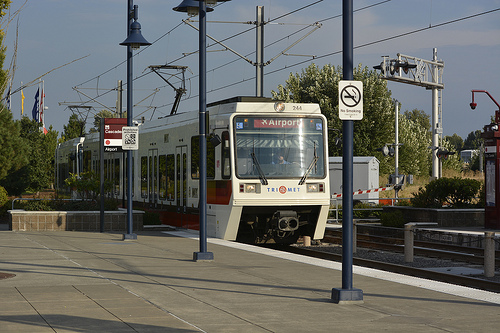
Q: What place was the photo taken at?
A: It was taken at the pavement.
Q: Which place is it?
A: It is a pavement.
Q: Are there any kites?
A: No, there are no kites.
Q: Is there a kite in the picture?
A: No, there are no kites.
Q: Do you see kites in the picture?
A: No, there are no kites.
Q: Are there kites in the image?
A: No, there are no kites.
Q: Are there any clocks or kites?
A: No, there are no kites or clocks.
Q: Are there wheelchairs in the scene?
A: No, there are no wheelchairs.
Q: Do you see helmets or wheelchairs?
A: No, there are no wheelchairs or helmets.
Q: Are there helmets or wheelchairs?
A: No, there are no wheelchairs or helmets.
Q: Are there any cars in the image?
A: No, there are no cars.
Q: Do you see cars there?
A: No, there are no cars.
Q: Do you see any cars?
A: No, there are no cars.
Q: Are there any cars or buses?
A: No, there are no cars or buses.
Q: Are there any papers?
A: No, there are no papers.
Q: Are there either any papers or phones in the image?
A: No, there are no papers or phones.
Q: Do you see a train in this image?
A: Yes, there is a train.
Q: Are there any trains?
A: Yes, there is a train.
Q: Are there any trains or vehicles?
A: Yes, there is a train.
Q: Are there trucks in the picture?
A: No, there are no trucks.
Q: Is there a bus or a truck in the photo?
A: No, there are no trucks or buses.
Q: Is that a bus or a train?
A: That is a train.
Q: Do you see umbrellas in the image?
A: No, there are no umbrellas.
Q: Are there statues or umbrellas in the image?
A: No, there are no umbrellas or statues.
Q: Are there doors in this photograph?
A: Yes, there are doors.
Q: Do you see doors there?
A: Yes, there are doors.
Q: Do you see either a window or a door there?
A: Yes, there are doors.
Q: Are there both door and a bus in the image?
A: No, there are doors but no buses.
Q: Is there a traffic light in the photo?
A: No, there are no traffic lights.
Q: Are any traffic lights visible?
A: No, there are no traffic lights.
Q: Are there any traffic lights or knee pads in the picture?
A: No, there are no traffic lights or knee pads.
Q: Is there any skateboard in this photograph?
A: No, there are no skateboards.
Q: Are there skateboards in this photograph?
A: No, there are no skateboards.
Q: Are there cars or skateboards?
A: No, there are no skateboards or cars.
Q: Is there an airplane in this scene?
A: No, there are no airplanes.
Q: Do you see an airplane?
A: No, there are no airplanes.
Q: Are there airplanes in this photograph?
A: No, there are no airplanes.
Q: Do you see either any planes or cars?
A: No, there are no planes or cars.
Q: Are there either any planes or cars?
A: No, there are no planes or cars.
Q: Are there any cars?
A: No, there are no cars.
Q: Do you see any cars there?
A: No, there are no cars.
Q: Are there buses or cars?
A: No, there are no cars or buses.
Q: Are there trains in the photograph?
A: Yes, there is a train.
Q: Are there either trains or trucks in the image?
A: Yes, there is a train.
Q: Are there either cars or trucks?
A: No, there are no cars or trucks.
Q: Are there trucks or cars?
A: No, there are no cars or trucks.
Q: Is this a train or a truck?
A: This is a train.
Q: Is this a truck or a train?
A: This is a train.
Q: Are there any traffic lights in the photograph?
A: No, there are no traffic lights.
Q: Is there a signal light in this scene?
A: No, there are no traffic lights.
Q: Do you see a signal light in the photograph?
A: No, there are no traffic lights.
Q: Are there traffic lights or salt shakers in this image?
A: No, there are no traffic lights or salt shakers.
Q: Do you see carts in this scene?
A: No, there are no carts.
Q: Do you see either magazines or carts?
A: No, there are no carts or magazines.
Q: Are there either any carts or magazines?
A: No, there are no carts or magazines.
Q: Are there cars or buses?
A: No, there are no cars or buses.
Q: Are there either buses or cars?
A: No, there are no cars or buses.